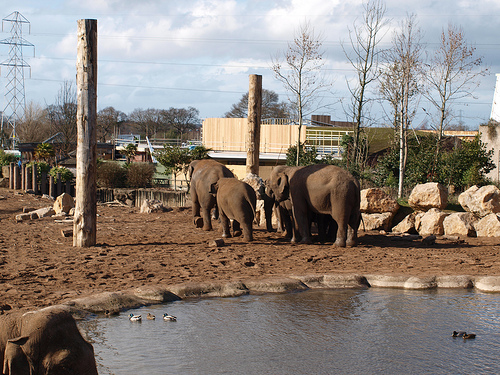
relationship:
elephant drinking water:
[0, 307, 97, 375] [73, 287, 499, 371]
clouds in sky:
[2, 5, 499, 123] [2, 3, 498, 141]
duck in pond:
[160, 309, 180, 324] [81, 290, 499, 373]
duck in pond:
[147, 313, 156, 321] [81, 290, 499, 373]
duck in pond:
[128, 313, 142, 323] [81, 290, 499, 373]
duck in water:
[459, 327, 479, 341] [73, 287, 499, 371]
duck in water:
[448, 325, 467, 337] [73, 287, 499, 371]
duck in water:
[162, 313, 177, 323] [73, 287, 499, 371]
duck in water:
[143, 306, 159, 318] [73, 287, 499, 371]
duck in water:
[126, 309, 142, 322] [73, 287, 499, 371]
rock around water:
[473, 270, 499, 294] [73, 287, 499, 371]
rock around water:
[429, 275, 472, 289] [73, 287, 499, 371]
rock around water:
[403, 272, 438, 291] [73, 287, 499, 371]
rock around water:
[322, 272, 365, 289] [73, 287, 499, 371]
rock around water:
[243, 273, 308, 293] [73, 287, 499, 371]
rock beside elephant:
[353, 183, 401, 207] [259, 161, 371, 248]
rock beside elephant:
[355, 210, 400, 233] [259, 161, 371, 248]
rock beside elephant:
[404, 177, 447, 209] [259, 161, 371, 248]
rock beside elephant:
[412, 205, 452, 236] [259, 161, 371, 248]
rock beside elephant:
[437, 205, 479, 237] [259, 161, 371, 248]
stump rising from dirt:
[69, 17, 99, 250] [3, 189, 498, 308]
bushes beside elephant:
[338, 123, 498, 206] [259, 161, 371, 248]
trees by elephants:
[272, 10, 473, 197] [179, 150, 373, 254]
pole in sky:
[2, 1, 43, 166] [2, 3, 498, 141]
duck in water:
[462, 333, 477, 340] [75, 294, 496, 370]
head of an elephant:
[12, 299, 99, 373] [0, 307, 97, 375]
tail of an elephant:
[241, 188, 264, 218] [204, 170, 262, 248]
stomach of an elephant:
[302, 186, 334, 220] [270, 157, 366, 244]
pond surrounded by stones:
[81, 290, 499, 373] [26, 274, 498, 315]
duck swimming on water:
[162, 313, 177, 323] [73, 287, 499, 371]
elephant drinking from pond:
[2, 297, 92, 373] [81, 290, 499, 373]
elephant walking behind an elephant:
[209, 177, 259, 242] [182, 163, 231, 243]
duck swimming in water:
[452, 331, 466, 337] [86, 268, 498, 364]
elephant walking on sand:
[266, 157, 360, 244] [2, 184, 498, 329]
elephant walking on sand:
[209, 177, 259, 242] [2, 184, 498, 329]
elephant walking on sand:
[182, 159, 236, 226] [2, 184, 498, 329]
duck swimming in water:
[162, 313, 177, 323] [73, 287, 499, 371]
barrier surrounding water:
[69, 261, 497, 318] [73, 287, 499, 371]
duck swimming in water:
[128, 313, 142, 323] [73, 287, 499, 371]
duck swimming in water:
[147, 313, 156, 321] [73, 287, 499, 371]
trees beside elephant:
[278, 9, 494, 195] [256, 156, 363, 250]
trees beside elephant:
[278, 9, 494, 195] [210, 173, 261, 245]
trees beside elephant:
[278, 9, 494, 195] [180, 153, 234, 234]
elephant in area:
[209, 177, 259, 242] [2, 152, 496, 371]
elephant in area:
[174, 154, 232, 234] [2, 152, 496, 371]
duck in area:
[128, 313, 142, 323] [2, 152, 496, 371]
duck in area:
[147, 313, 156, 321] [2, 152, 496, 371]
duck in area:
[162, 313, 177, 323] [2, 152, 496, 371]